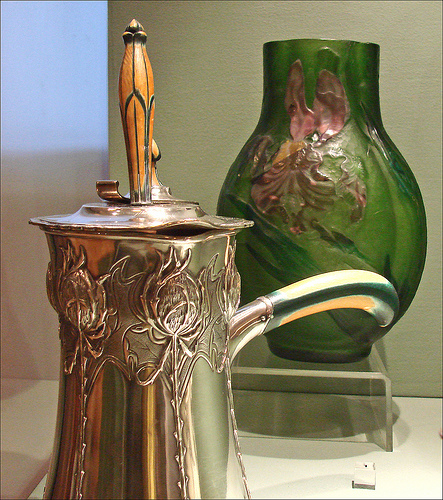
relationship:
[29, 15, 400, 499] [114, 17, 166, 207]
canister has handle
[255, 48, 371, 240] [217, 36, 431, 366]
glass design on side of vase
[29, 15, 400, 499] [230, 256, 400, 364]
canister has spout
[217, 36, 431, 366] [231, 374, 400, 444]
vase has shadow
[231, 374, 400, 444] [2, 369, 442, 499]
shadow across display table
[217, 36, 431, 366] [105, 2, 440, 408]
vase sitting by wall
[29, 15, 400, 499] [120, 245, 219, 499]
canister has foral design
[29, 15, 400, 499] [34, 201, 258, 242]
canister has top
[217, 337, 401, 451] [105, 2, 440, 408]
display by wall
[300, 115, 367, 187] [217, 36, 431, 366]
light reflection on side of vase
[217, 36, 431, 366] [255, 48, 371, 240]
vase has glass design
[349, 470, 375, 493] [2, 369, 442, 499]
clip on top of display table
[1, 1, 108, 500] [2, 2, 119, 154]
wall has blue color